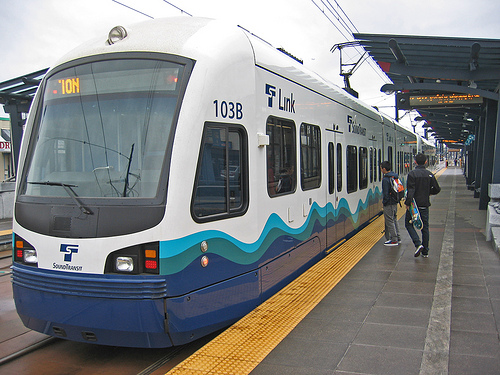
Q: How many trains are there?
A: One.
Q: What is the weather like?
A: Sunny.